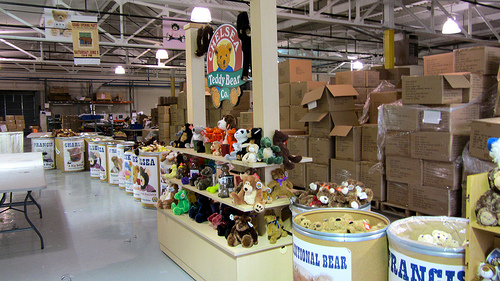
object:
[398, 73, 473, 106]
box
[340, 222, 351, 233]
bear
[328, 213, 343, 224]
bear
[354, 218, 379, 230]
bear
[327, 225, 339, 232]
bear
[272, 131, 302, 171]
stuffed animal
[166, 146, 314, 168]
shelf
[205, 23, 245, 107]
banner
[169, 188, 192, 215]
bear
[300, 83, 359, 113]
boxes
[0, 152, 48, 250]
folding table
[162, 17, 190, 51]
sign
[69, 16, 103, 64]
sign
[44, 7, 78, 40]
sign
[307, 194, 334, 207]
toy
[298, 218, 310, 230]
toy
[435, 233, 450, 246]
toy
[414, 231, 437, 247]
toy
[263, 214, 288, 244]
bear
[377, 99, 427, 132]
boxes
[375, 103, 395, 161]
plastic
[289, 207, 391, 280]
barrel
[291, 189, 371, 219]
barrel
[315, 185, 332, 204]
stuffed animal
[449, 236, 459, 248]
stuffed animal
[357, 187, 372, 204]
stuffed animal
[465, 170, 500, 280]
display cabinet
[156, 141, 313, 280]
display cabinet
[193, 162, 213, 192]
teddy bear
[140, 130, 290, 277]
three shelves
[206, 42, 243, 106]
teddy bear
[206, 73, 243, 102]
written white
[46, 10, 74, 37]
teddy bear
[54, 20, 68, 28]
white shirt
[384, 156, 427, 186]
boxes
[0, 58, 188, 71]
line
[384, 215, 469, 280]
barrel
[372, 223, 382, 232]
toys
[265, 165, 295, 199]
stuffed animal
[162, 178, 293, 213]
shelves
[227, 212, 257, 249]
stuffed animal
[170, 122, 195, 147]
stuffed animals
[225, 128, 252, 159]
bears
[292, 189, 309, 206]
toys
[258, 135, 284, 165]
animal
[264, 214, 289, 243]
animal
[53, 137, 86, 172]
barrel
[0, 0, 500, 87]
ceiling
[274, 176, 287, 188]
ribbon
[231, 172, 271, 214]
toys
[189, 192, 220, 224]
toys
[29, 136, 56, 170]
bins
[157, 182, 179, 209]
stuffed animals